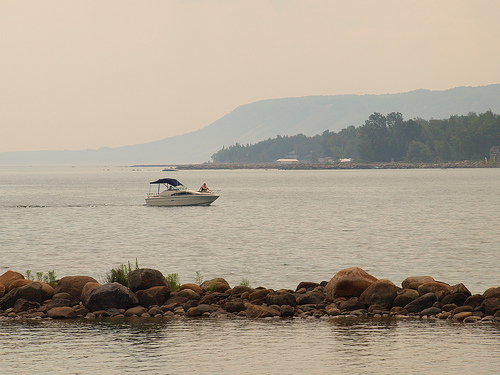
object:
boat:
[145, 177, 220, 206]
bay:
[0, 167, 500, 375]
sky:
[0, 0, 500, 154]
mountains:
[1, 82, 498, 171]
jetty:
[2, 268, 498, 332]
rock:
[2, 267, 499, 328]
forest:
[209, 108, 500, 161]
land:
[125, 160, 499, 170]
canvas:
[150, 178, 185, 187]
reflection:
[2, 316, 495, 375]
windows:
[171, 192, 199, 196]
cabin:
[159, 189, 213, 196]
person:
[197, 183, 210, 192]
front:
[202, 190, 219, 205]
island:
[162, 168, 177, 171]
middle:
[167, 169, 177, 176]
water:
[0, 167, 500, 375]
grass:
[25, 258, 250, 293]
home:
[489, 146, 500, 161]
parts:
[97, 290, 130, 296]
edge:
[166, 160, 499, 168]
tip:
[216, 194, 220, 198]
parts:
[150, 197, 158, 199]